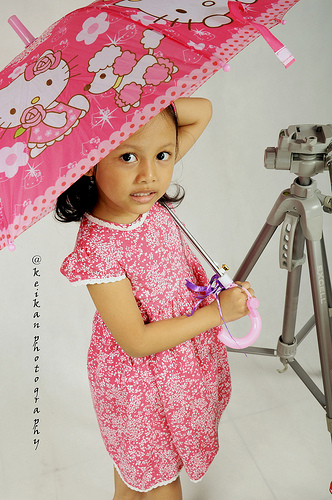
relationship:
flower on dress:
[124, 414, 145, 436] [61, 214, 231, 492]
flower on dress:
[157, 447, 176, 476] [51, 212, 248, 500]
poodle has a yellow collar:
[85, 28, 177, 111] [111, 74, 122, 92]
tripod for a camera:
[266, 124, 331, 498] [262, 120, 331, 185]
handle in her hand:
[220, 284, 263, 349] [218, 285, 249, 324]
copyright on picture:
[31, 255, 44, 452] [1, 2, 331, 500]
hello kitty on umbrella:
[0, 50, 89, 155] [2, 1, 297, 98]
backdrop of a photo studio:
[302, 3, 331, 126] [1, 2, 331, 500]